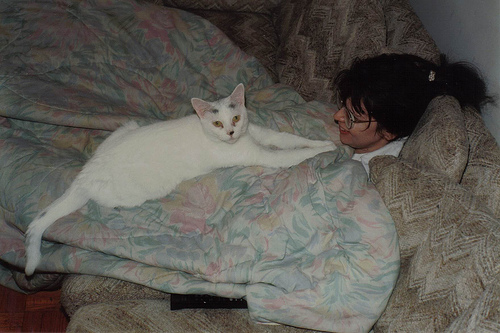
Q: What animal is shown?
A: A cat.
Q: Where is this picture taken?
A: A bedroom.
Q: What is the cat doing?
A: Laying down.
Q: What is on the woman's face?
A: Glasses.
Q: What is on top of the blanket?
A: Cat.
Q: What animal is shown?
A: Cat.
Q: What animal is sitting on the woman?
A: Cat.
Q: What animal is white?
A: Cat.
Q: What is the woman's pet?
A: Cat.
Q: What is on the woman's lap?
A: Cat.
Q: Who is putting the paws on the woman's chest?
A: Cat.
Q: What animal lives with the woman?
A: Cat.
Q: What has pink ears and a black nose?
A: Cat.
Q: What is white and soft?
A: The cat.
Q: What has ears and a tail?
A: The cat.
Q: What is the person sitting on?
A: A couch.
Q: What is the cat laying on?
A: A blanket.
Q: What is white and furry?
A: The cat.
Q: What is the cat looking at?
A: The camera.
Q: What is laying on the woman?
A: A cat.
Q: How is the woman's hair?
A: In a ponytail.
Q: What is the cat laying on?
A: A woman.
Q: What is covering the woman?
A: A blanket.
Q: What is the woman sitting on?
A: A couch.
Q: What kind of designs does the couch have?
A: Zig zag.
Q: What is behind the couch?
A: A wall.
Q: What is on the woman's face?
A: Glasses.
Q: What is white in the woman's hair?
A: A hair tie.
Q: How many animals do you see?
A: 1.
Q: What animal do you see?
A: Cat.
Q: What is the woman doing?
A: Sitting down.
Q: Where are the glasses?
A: On the woman's head.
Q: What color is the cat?
A: White.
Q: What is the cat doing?
A: Laying down on the woman.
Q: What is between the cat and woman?
A: A blanket.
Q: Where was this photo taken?
A: On the bed.